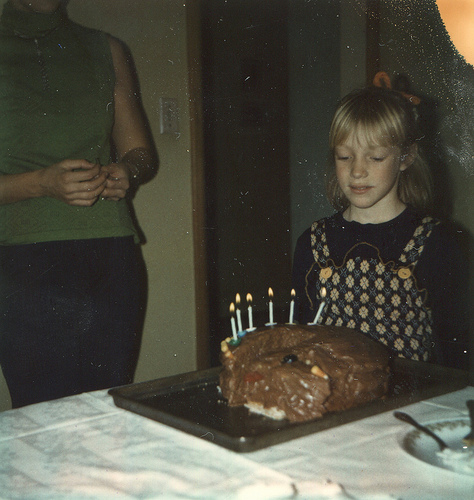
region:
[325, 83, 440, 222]
Blonde hair on girl's head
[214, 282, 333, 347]
Candles on a cake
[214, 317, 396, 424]
Chocolate frosting on cake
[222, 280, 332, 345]
Six candles are lit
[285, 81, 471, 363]
Girl is wearing suspenders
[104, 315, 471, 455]
Cake is on a tray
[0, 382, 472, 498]
White tablecloth on the table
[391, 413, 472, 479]
A round white plate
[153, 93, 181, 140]
Light switch on the wall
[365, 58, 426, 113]
Orange ribbon in girl's hair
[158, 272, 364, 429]
a cake on the tray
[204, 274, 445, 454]
a cake on the tray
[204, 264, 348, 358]
candles on the cake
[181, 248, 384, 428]
candles on the cake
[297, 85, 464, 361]
The girl has a blond hair.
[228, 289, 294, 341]
There are five candles over the cake.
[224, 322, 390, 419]
The chocolate cake is over the tray.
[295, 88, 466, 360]
The girl is looking for the cake.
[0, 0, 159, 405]
The woman is wearing a green shirt and blue jeans.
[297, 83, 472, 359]
The girls is celebrating her sixth birthday.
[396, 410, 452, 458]
The spoon in on the dish.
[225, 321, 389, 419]
The cake flavor is chocolate.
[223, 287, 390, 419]
The cake has six candles on it.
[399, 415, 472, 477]
The plate has a spoon on it.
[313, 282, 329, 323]
candle on a cake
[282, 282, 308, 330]
candle on a cake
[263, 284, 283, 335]
candle on a cake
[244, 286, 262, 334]
candle on a cake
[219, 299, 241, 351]
candle on a cake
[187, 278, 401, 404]
cake on a pan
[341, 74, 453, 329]
girl wearing a dress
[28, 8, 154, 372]
woman wearing green shirt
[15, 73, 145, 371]
woman wearing black pants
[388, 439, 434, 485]
plate on a table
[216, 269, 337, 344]
the lit candles of a birthday cake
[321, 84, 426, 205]
the head of a girl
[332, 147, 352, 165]
the eye of a girl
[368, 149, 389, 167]
the eye of a girl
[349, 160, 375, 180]
the nose of a girl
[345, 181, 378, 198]
the mouth of a girl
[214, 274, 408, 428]
a chocolate birthday cake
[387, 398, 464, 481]
a fork on a plate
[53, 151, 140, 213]
the hands of a person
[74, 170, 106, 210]
the fingers of a hand